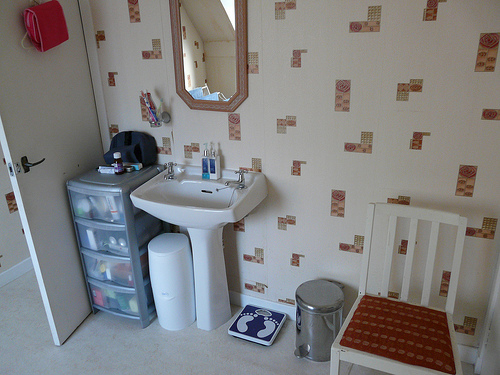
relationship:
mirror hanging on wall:
[166, 1, 251, 112] [76, 0, 497, 363]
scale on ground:
[229, 300, 283, 345] [109, 321, 249, 373]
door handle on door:
[24, 157, 47, 170] [9, 70, 111, 350]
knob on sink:
[225, 168, 246, 188] [131, 161, 269, 329]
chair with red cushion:
[321, 195, 464, 373] [332, 285, 458, 374]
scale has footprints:
[229, 300, 283, 345] [239, 279, 332, 369]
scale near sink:
[221, 300, 283, 345] [102, 129, 407, 359]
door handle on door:
[24, 157, 47, 170] [0, 0, 103, 346]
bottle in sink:
[209, 143, 225, 178] [131, 161, 269, 329]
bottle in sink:
[201, 143, 214, 177] [131, 161, 269, 329]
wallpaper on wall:
[298, 63, 456, 162] [76, 0, 497, 363]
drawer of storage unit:
[65, 183, 133, 224] [23, 12, 463, 362]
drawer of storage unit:
[65, 183, 133, 224] [55, 159, 177, 330]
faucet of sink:
[220, 168, 244, 198] [130, 160, 265, 240]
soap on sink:
[207, 141, 220, 180] [131, 161, 269, 329]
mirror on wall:
[166, 1, 251, 112] [86, 2, 493, 334]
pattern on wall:
[450, 162, 484, 204] [76, 0, 497, 363]